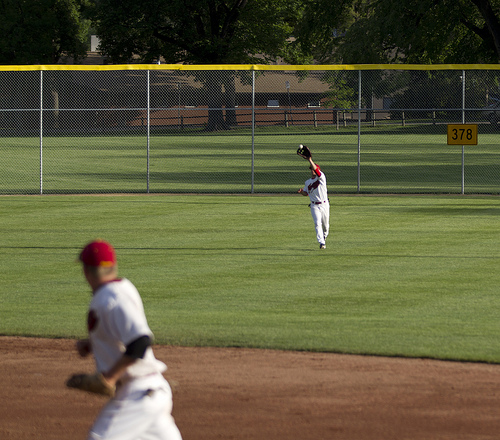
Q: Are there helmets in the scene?
A: No, there are no helmets.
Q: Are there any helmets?
A: No, there are no helmets.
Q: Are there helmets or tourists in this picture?
A: No, there are no helmets or tourists.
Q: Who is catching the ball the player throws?
A: The man is catching the ball.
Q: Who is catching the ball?
A: The man is catching the ball.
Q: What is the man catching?
A: The man is catching the ball.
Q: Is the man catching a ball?
A: Yes, the man is catching a ball.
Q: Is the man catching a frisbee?
A: No, the man is catching a ball.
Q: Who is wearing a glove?
A: The man is wearing a glove.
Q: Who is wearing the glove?
A: The man is wearing a glove.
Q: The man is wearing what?
A: The man is wearing a glove.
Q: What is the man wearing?
A: The man is wearing a glove.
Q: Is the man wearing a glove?
A: Yes, the man is wearing a glove.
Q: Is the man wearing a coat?
A: No, the man is wearing a glove.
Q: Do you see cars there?
A: No, there are no cars.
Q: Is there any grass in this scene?
A: Yes, there is grass.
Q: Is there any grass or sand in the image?
A: Yes, there is grass.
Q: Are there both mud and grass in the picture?
A: No, there is grass but no mud.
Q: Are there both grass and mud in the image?
A: No, there is grass but no mud.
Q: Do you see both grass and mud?
A: No, there is grass but no mud.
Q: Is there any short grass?
A: Yes, there is short grass.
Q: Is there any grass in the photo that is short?
A: Yes, there is grass that is short.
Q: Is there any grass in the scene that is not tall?
A: Yes, there is short grass.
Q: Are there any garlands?
A: No, there are no garlands.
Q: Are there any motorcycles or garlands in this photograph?
A: No, there are no garlands or motorcycles.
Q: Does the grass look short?
A: Yes, the grass is short.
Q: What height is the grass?
A: The grass is short.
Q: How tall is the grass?
A: The grass is short.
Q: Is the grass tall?
A: No, the grass is short.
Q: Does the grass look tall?
A: No, the grass is short.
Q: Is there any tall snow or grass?
A: No, there is grass but it is short.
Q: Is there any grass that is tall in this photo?
A: No, there is grass but it is short.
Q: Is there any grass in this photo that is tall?
A: No, there is grass but it is short.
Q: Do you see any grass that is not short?
A: No, there is grass but it is short.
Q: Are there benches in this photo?
A: No, there are no benches.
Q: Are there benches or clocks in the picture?
A: No, there are no benches or clocks.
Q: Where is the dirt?
A: The dirt is in the grass.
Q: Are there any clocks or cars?
A: No, there are no cars or clocks.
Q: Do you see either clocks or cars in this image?
A: No, there are no cars or clocks.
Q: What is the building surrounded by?
A: The building is surrounded by the fence.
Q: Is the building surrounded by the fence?
A: Yes, the building is surrounded by the fence.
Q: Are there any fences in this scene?
A: Yes, there is a fence.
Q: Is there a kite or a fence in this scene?
A: Yes, there is a fence.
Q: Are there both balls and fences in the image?
A: Yes, there are both a fence and a ball.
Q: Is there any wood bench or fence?
A: Yes, there is a wood fence.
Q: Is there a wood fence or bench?
A: Yes, there is a wood fence.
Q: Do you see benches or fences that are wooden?
A: Yes, the fence is wooden.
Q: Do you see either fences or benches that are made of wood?
A: Yes, the fence is made of wood.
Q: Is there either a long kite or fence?
A: Yes, there is a long fence.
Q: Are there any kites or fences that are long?
A: Yes, the fence is long.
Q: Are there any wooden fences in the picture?
A: Yes, there is a wood fence.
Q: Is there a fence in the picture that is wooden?
A: Yes, there is a fence that is wooden.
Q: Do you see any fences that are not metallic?
A: Yes, there is a wooden fence.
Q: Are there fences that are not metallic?
A: Yes, there is a wooden fence.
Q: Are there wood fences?
A: Yes, there is a fence that is made of wood.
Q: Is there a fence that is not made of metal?
A: Yes, there is a fence that is made of wood.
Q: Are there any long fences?
A: Yes, there is a long fence.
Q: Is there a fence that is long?
A: Yes, there is a fence that is long.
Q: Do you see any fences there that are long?
A: Yes, there is a fence that is long.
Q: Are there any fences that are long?
A: Yes, there is a fence that is long.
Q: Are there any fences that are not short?
A: Yes, there is a long fence.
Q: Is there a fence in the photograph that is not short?
A: Yes, there is a long fence.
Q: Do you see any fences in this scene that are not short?
A: Yes, there is a long fence.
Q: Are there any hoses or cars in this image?
A: No, there are no cars or hoses.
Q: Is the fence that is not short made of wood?
A: Yes, the fence is made of wood.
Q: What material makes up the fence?
A: The fence is made of wood.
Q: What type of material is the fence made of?
A: The fence is made of wood.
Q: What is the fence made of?
A: The fence is made of wood.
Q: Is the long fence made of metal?
A: No, the fence is made of wood.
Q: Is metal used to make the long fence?
A: No, the fence is made of wood.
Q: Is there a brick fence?
A: No, there is a fence but it is made of wood.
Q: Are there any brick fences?
A: No, there is a fence but it is made of wood.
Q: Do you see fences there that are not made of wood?
A: No, there is a fence but it is made of wood.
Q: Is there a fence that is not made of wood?
A: No, there is a fence but it is made of wood.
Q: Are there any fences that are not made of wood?
A: No, there is a fence but it is made of wood.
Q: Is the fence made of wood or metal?
A: The fence is made of wood.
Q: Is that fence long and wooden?
A: Yes, the fence is long and wooden.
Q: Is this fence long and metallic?
A: No, the fence is long but wooden.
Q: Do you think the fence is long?
A: Yes, the fence is long.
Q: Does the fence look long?
A: Yes, the fence is long.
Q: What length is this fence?
A: The fence is long.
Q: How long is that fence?
A: The fence is long.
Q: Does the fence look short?
A: No, the fence is long.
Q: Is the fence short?
A: No, the fence is long.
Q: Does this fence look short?
A: No, the fence is long.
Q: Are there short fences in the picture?
A: No, there is a fence but it is long.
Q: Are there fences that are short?
A: No, there is a fence but it is long.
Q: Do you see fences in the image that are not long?
A: No, there is a fence but it is long.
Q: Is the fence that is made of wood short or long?
A: The fence is long.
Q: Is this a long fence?
A: Yes, this is a long fence.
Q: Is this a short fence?
A: No, this is a long fence.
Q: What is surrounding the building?
A: The fence is surrounding the building.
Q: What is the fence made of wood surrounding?
A: The fence is surrounding the building.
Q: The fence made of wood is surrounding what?
A: The fence is surrounding the building.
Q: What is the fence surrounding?
A: The fence is surrounding the building.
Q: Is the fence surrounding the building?
A: Yes, the fence is surrounding the building.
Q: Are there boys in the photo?
A: No, there are no boys.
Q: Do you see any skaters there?
A: No, there are no skaters.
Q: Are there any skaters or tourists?
A: No, there are no skaters or tourists.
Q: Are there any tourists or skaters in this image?
A: No, there are no skaters or tourists.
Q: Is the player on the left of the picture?
A: Yes, the player is on the left of the image.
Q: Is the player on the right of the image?
A: No, the player is on the left of the image.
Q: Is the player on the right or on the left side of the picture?
A: The player is on the left of the image.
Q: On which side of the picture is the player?
A: The player is on the left of the image.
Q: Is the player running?
A: Yes, the player is running.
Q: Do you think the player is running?
A: Yes, the player is running.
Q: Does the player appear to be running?
A: Yes, the player is running.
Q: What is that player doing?
A: The player is running.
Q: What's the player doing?
A: The player is running.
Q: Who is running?
A: The player is running.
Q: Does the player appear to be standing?
A: No, the player is running.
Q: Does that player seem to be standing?
A: No, the player is running.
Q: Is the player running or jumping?
A: The player is running.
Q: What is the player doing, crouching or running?
A: The player is running.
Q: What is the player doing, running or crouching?
A: The player is running.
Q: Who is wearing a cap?
A: The player is wearing a cap.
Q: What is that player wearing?
A: The player is wearing a cap.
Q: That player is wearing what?
A: The player is wearing a cap.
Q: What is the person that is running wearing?
A: The player is wearing a cap.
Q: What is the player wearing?
A: The player is wearing a cap.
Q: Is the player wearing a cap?
A: Yes, the player is wearing a cap.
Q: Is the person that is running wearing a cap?
A: Yes, the player is wearing a cap.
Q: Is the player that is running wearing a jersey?
A: No, the player is wearing a cap.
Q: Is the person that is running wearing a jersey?
A: No, the player is wearing a cap.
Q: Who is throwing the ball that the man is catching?
A: The player is throwing the ball.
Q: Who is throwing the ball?
A: The player is throwing the ball.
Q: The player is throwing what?
A: The player is throwing the ball.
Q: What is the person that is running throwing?
A: The player is throwing the ball.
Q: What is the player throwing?
A: The player is throwing the ball.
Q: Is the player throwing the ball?
A: Yes, the player is throwing the ball.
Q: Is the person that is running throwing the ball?
A: Yes, the player is throwing the ball.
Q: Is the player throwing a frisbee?
A: No, the player is throwing the ball.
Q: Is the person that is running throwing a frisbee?
A: No, the player is throwing the ball.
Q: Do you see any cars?
A: No, there are no cars.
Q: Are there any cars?
A: No, there are no cars.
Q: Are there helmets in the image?
A: No, there are no helmets.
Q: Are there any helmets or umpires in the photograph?
A: No, there are no helmets or umpires.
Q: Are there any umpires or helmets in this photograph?
A: No, there are no helmets or umpires.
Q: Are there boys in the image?
A: No, there are no boys.